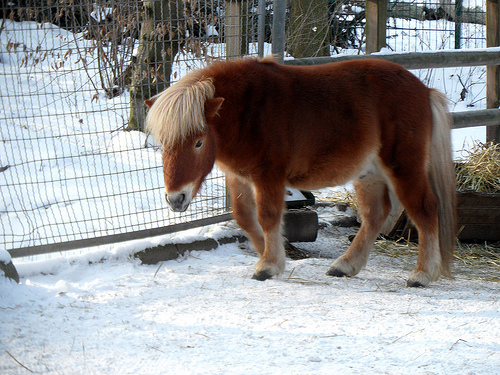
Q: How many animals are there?
A: One.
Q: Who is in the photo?
A: A donkey.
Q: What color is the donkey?
A: Brown.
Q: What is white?
A: The snow.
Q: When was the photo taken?
A: Day time.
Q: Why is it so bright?
A: Sun light.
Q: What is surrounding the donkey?
A: A fence.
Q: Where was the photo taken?
A: Near a zoo cage.